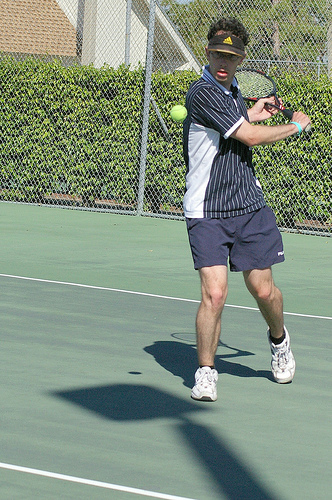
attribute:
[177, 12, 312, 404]
man — brunette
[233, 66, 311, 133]
racket — black, red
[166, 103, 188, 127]
tennis ball — green, yellow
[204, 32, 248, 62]
visor — black, yellow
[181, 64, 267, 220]
shirt — blue, white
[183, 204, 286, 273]
shorts — white, blue, black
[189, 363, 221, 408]
shoe — white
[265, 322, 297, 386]
shoe — white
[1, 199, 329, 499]
court — green, white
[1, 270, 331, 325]
line — white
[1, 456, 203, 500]
line — white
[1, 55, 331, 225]
bush hedge — green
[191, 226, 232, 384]
leg — hairy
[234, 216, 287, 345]
leg — hairy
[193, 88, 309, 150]
arm — bare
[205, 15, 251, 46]
hair — curly, black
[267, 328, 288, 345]
sock — black, short